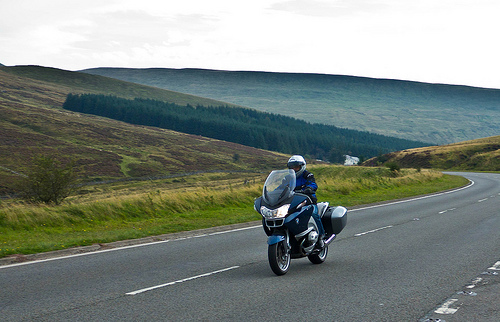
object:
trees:
[63, 91, 437, 163]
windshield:
[262, 169, 296, 207]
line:
[438, 207, 456, 214]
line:
[353, 224, 393, 236]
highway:
[0, 165, 500, 322]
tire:
[307, 240, 328, 265]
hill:
[0, 64, 500, 230]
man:
[262, 155, 325, 249]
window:
[262, 169, 297, 207]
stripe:
[353, 197, 488, 237]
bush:
[22, 150, 76, 206]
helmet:
[287, 155, 307, 178]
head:
[289, 162, 301, 172]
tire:
[268, 240, 292, 275]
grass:
[0, 63, 500, 259]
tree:
[0, 151, 87, 207]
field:
[0, 67, 469, 267]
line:
[124, 265, 240, 296]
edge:
[0, 226, 238, 269]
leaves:
[9, 165, 73, 190]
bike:
[253, 169, 347, 276]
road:
[0, 170, 500, 322]